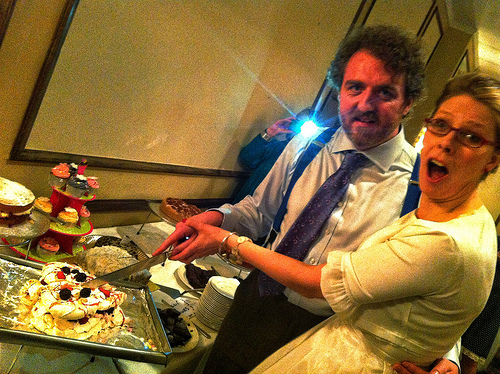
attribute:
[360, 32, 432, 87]
curly hair — brown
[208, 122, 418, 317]
shirt — LONG SLEEVED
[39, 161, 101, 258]
display — colorful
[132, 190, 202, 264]
display — colorful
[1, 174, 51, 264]
display — colorful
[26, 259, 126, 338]
cake — heart shaped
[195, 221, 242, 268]
bracelets — shiny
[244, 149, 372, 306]
tie — blue, silk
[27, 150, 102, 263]
platter — red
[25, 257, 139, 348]
cake frosting — WHITE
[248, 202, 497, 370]
dress — WHITE, LONG SLEEVED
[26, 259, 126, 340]
dessert — heart shaped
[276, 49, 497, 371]
woman — LONG SLEEVED, WHITE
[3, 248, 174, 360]
sheet — METAL, RECTANGLE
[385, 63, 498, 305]
woman — SURPRISED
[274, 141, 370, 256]
tie — purple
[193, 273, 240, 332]
plates — white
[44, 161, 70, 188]
cupcake — ASSORTED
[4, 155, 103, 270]
tower — RED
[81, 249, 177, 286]
knife — long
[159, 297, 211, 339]
knife — long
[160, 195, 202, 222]
pie — chocolate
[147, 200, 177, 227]
tray — metal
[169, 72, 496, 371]
woman — wearing white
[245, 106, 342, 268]
suspenders — blue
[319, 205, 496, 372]
dress — white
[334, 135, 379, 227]
tie — BLUE PATTERNED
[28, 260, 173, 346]
cake — HEART SHAPED